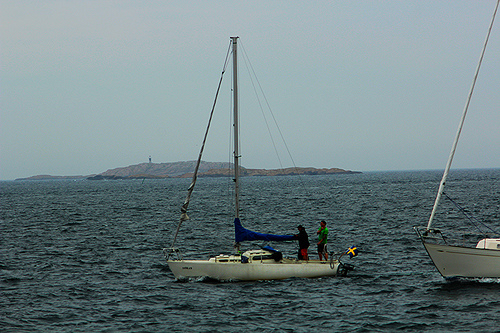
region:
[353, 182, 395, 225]
the water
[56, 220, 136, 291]
the water in the ocean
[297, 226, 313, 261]
a person on a boat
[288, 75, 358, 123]
the sky is clear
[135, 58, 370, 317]
a boat on the water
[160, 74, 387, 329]
a small boat on the water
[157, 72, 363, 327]
a sail boat on teh water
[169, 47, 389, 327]
a sailboat with mast down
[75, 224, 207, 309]
a body of water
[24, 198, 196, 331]
a body of calm water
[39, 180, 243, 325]
a body of choppy water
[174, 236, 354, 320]
a white sail boat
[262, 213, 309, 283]
a person on a boat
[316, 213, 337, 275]
a person on a boat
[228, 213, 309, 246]
the sail is blue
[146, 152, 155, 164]
a large statue in the background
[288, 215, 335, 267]
two people stand on the deck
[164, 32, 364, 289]
a small sailboat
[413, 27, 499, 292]
a larger sailboat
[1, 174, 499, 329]
the water surface is slightly choppy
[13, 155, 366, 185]
an island in the background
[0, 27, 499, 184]
the sky is clear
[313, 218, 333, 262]
man wearing a green shirt and blue shorts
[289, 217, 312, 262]
person wearing blue and red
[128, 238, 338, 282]
white boat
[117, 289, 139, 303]
white and gray ocean waves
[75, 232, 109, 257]
white and gray ocean waves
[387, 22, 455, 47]
white clouds in blue sky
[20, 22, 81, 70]
white clouds in blue sky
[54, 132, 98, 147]
white clouds in blue sky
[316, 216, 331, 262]
man in green on a boat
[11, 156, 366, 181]
island in the background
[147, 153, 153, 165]
lighthouse on the island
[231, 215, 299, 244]
blue sail on the boat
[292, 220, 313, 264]
person in black and red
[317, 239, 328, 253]
black shorts on a man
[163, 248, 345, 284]
white sailboat holding two people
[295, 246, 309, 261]
red and black shorts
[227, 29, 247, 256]
mast of the boat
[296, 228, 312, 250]
black tee shirt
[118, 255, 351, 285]
a white boat on water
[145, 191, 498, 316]
two boats on the water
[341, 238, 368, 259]
a yellow cross on blue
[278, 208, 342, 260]
two people standing on the boat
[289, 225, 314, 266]
the woman on the boat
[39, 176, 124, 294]
the water is rough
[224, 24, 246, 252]
mast of boat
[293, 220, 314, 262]
person on boat with something red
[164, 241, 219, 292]
front part of boat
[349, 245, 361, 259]
flag on back of boat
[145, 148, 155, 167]
lighthouse in distance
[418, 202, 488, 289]
front of larger boat on right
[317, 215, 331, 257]
person in green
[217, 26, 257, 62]
very top of mast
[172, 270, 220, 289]
wave on front of boat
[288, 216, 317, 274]
woman on the boat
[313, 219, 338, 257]
man on the boat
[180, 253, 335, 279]
the boat is white in color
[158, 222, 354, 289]
the boat is on the water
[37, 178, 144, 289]
the water is rippled